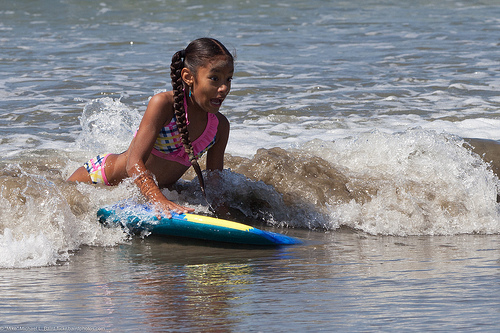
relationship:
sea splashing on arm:
[1, 1, 498, 331] [131, 97, 171, 214]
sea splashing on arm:
[1, 1, 498, 331] [209, 119, 232, 200]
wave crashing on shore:
[224, 126, 497, 237] [0, 234, 497, 328]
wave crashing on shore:
[0, 96, 497, 267] [0, 234, 497, 328]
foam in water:
[305, 83, 361, 113] [265, 120, 497, 328]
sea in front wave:
[1, 1, 498, 331] [4, 128, 482, 246]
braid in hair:
[159, 53, 217, 190] [164, 36, 252, 211]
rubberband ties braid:
[181, 147, 203, 169] [167, 50, 196, 207]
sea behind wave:
[1, 1, 498, 331] [12, 118, 469, 275]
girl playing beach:
[63, 37, 233, 219] [6, 227, 498, 326]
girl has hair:
[63, 37, 233, 219] [170, 37, 236, 198]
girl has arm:
[63, 37, 233, 219] [205, 112, 230, 170]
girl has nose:
[63, 37, 233, 219] [217, 80, 227, 93]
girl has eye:
[61, 30, 253, 238] [205, 74, 219, 83]